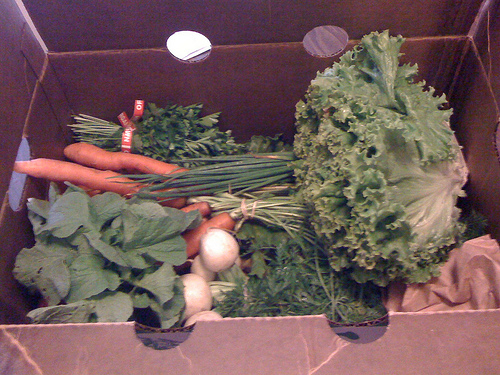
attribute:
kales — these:
[16, 195, 182, 327]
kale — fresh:
[131, 210, 184, 271]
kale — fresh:
[51, 208, 100, 255]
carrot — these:
[63, 146, 184, 178]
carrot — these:
[9, 157, 146, 192]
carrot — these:
[155, 189, 185, 206]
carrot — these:
[180, 197, 211, 217]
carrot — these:
[173, 210, 233, 255]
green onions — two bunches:
[100, 150, 302, 212]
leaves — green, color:
[15, 189, 200, 344]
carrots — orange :
[11, 140, 185, 197]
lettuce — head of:
[287, 30, 477, 282]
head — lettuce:
[296, 27, 471, 271]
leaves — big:
[290, 23, 471, 288]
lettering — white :
[120, 118, 138, 158]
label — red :
[105, 73, 186, 154]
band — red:
[110, 96, 146, 150]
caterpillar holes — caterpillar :
[27, 265, 50, 297]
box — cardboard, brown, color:
[0, 3, 497, 372]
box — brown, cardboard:
[4, 33, 499, 348]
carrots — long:
[19, 131, 188, 191]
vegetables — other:
[61, 114, 491, 321]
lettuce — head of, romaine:
[285, 80, 496, 249]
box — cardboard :
[18, 158, 486, 375]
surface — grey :
[37, 19, 417, 48]